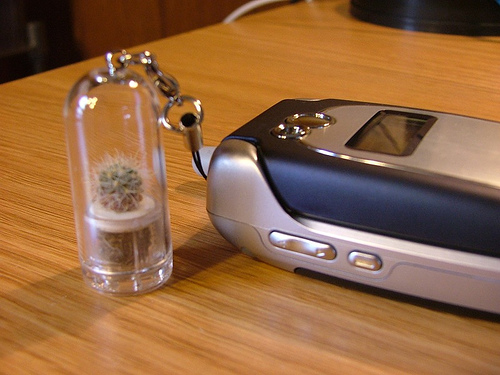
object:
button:
[346, 249, 384, 272]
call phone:
[189, 95, 500, 314]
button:
[268, 230, 337, 260]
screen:
[343, 107, 440, 157]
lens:
[271, 123, 310, 140]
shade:
[173, 220, 259, 280]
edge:
[78, 263, 175, 298]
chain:
[115, 49, 205, 153]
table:
[0, 0, 499, 375]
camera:
[269, 109, 337, 140]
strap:
[116, 48, 207, 181]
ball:
[84, 148, 153, 213]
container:
[61, 64, 176, 297]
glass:
[60, 46, 176, 297]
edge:
[134, 252, 174, 287]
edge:
[78, 262, 131, 294]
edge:
[159, 207, 172, 243]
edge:
[59, 100, 68, 134]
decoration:
[64, 48, 175, 298]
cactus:
[95, 162, 146, 214]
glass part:
[115, 152, 161, 230]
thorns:
[104, 157, 115, 166]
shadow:
[0, 218, 289, 357]